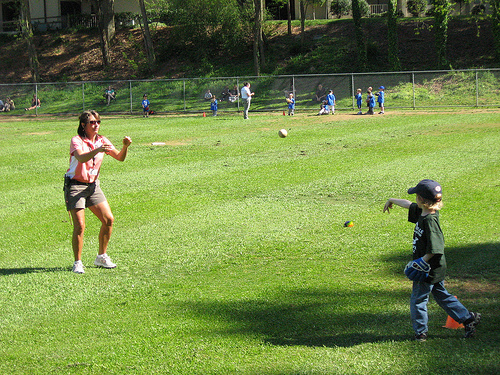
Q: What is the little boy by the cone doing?
A: Throwing a ball.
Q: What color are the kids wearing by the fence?
A: Blue.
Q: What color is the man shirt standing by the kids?
A: White.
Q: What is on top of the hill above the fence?
A: Trees.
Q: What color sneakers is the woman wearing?
A: White.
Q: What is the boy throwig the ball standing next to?
A: Cone.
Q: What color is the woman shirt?
A: Red and white.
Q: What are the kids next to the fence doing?
A: Playing.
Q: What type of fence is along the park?
A: Chain link.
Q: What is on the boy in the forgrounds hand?
A: Baseball glove.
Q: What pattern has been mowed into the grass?
A: Stripes.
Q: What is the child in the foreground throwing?
A: Baseball.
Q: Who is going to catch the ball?
A: Woman with pink shirt.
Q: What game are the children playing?
A: Baseball.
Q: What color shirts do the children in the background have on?
A: Blue.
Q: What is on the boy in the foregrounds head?
A: Baseball hat.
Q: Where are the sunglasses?
A: On woman in pink shirts face.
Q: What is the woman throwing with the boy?
A: A ball.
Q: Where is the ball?
A: In the air.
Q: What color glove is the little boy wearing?
A: Blue.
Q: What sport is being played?
A: Baseball.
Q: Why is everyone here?
A: They have a game today.